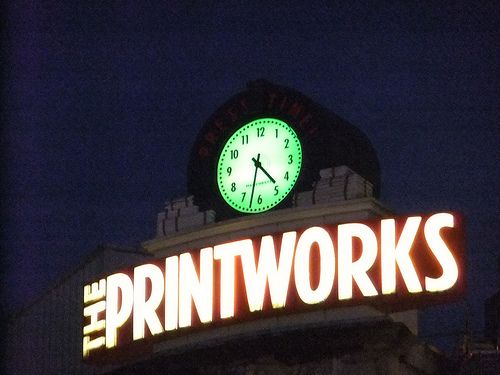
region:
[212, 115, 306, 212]
A clock in the photo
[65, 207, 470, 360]
Signage in the photo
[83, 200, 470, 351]
Text on the signage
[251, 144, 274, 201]
Arms in the clock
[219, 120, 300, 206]
Light on the clock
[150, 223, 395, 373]
A building in the photo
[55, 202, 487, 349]
Red light on the edges of text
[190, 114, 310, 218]
Green and white color on the clock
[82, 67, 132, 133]
Dark blue skies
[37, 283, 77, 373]
Wall of a building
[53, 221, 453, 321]
lighted sign on a building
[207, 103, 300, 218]
clock with neon green light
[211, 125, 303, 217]
clock shows the time as 4:32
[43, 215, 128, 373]
cables from a suspension bridge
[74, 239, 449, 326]
sign for business is in all capital letters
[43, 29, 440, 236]
the sky is dark because it is night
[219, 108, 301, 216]
clock is lit up to be visable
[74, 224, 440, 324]
the name of a business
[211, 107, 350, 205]
the clock is on the top of a building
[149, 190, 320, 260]
building features are cement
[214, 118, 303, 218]
green neon clock face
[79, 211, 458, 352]
white sign reading the printworks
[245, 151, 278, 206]
black hands on clockface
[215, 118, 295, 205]
black numbers on clock face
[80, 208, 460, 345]
red glow behind white lights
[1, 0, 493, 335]
dark blue night sky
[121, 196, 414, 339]
concrete top to building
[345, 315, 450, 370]
crumbled cinder blocks on top of building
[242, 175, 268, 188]
black letters on clock face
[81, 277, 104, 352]
letter the posted sideways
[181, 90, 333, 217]
glowing clock above sign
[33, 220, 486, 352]
neon sign on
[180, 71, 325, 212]
glowing clock on four thrity three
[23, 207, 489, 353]
a glowing sign for the printworks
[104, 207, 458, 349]
glowing red letters spelling printworks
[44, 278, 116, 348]
neon yellow letters spelling the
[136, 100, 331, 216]
clock glowing in the night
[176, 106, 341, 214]
clock glowing during late morning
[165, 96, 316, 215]
glowing clock with two hands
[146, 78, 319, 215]
clock has no seconds hand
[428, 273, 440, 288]
part of a light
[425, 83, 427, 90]
part of the sky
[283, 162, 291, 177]
part of a wall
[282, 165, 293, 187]
edge of a clock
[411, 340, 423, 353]
part of a building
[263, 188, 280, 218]
edge of a clock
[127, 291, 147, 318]
side of a building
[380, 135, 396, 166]
part of the sky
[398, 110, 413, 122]
part of a cloud